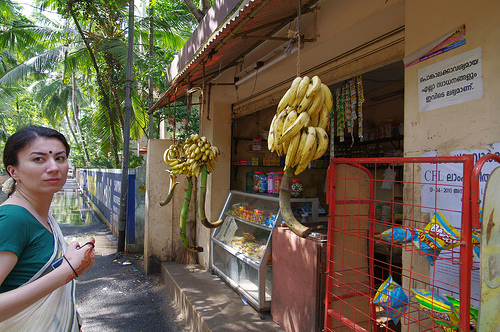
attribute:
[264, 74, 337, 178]
bananas — hanging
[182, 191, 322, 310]
counter — metal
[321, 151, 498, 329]
red shelf — holding food products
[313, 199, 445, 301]
food — is being sold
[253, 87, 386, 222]
bananas — yellow, bunched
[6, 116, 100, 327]
woman — wearing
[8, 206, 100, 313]
shirt — green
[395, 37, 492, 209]
signs — white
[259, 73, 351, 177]
bananas — hanging